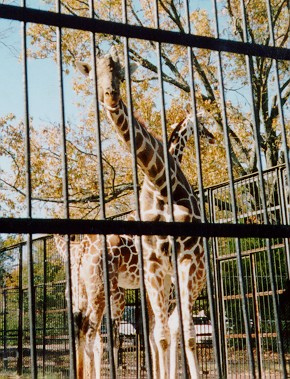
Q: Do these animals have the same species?
A: Yes, all the animals are giraffes.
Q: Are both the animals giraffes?
A: Yes, all the animals are giraffes.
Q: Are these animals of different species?
A: No, all the animals are giraffes.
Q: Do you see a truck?
A: No, there are no trucks.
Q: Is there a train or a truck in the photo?
A: No, there are no trucks or trains.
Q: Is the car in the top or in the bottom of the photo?
A: The car is in the bottom of the image.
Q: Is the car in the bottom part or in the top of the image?
A: The car is in the bottom of the image.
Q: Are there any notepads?
A: No, there are no notepads.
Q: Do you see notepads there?
A: No, there are no notepads.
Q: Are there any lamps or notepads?
A: No, there are no notepads or lamps.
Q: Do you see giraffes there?
A: Yes, there is a giraffe.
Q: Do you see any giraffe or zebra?
A: Yes, there is a giraffe.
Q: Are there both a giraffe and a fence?
A: Yes, there are both a giraffe and a fence.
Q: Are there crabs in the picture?
A: No, there are no crabs.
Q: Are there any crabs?
A: No, there are no crabs.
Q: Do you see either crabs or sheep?
A: No, there are no crabs or sheep.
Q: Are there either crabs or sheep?
A: No, there are no crabs or sheep.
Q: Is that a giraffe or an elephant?
A: That is a giraffe.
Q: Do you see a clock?
A: No, there are no clocks.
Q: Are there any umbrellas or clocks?
A: No, there are no clocks or umbrellas.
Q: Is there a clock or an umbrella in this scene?
A: No, there are no clocks or umbrellas.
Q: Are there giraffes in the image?
A: Yes, there is a giraffe.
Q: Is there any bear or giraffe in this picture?
A: Yes, there is a giraffe.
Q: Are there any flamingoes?
A: No, there are no flamingoes.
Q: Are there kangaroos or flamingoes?
A: No, there are no flamingoes or kangaroos.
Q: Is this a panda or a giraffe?
A: This is a giraffe.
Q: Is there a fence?
A: Yes, there is a fence.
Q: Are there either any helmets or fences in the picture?
A: Yes, there is a fence.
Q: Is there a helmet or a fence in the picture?
A: Yes, there is a fence.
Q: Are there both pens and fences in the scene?
A: No, there is a fence but no pens.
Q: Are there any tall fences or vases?
A: Yes, there is a tall fence.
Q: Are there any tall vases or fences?
A: Yes, there is a tall fence.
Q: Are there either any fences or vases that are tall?
A: Yes, the fence is tall.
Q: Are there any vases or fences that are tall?
A: Yes, the fence is tall.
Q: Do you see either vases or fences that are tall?
A: Yes, the fence is tall.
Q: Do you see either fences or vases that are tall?
A: Yes, the fence is tall.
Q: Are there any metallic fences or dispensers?
A: Yes, there is a metal fence.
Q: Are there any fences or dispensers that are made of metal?
A: Yes, the fence is made of metal.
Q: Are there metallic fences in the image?
A: Yes, there is a metal fence.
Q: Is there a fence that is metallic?
A: Yes, there is a fence that is metallic.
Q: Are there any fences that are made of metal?
A: Yes, there is a fence that is made of metal.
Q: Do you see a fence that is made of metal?
A: Yes, there is a fence that is made of metal.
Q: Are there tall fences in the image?
A: Yes, there is a tall fence.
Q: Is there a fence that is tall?
A: Yes, there is a fence that is tall.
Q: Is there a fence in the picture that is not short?
A: Yes, there is a tall fence.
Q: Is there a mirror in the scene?
A: No, there are no mirrors.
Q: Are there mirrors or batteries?
A: No, there are no mirrors or batteries.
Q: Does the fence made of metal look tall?
A: Yes, the fence is tall.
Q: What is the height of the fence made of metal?
A: The fence is tall.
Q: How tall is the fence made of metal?
A: The fence is tall.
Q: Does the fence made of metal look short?
A: No, the fence is tall.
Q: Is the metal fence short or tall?
A: The fence is tall.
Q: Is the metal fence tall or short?
A: The fence is tall.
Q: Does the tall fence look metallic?
A: Yes, the fence is metallic.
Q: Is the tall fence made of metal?
A: Yes, the fence is made of metal.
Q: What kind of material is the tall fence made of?
A: The fence is made of metal.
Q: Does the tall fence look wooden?
A: No, the fence is metallic.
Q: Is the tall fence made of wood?
A: No, the fence is made of metal.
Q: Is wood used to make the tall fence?
A: No, the fence is made of metal.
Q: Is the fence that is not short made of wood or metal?
A: The fence is made of metal.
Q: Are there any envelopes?
A: No, there are no envelopes.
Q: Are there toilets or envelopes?
A: No, there are no envelopes or toilets.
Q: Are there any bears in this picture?
A: No, there are no bears.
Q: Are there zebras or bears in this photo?
A: No, there are no bears or zebras.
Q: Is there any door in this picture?
A: Yes, there is a door.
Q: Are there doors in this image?
A: Yes, there is a door.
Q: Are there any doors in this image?
A: Yes, there is a door.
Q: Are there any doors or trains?
A: Yes, there is a door.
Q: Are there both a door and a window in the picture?
A: No, there is a door but no windows.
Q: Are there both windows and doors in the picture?
A: No, there is a door but no windows.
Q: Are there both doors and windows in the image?
A: No, there is a door but no windows.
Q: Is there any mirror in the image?
A: No, there are no mirrors.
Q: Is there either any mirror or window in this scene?
A: No, there are no mirrors or windows.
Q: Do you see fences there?
A: Yes, there is a fence.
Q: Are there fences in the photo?
A: Yes, there is a fence.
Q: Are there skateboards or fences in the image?
A: Yes, there is a fence.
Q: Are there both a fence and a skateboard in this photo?
A: No, there is a fence but no skateboards.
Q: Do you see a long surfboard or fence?
A: Yes, there is a long fence.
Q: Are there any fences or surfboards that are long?
A: Yes, the fence is long.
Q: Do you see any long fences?
A: Yes, there is a long fence.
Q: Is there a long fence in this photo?
A: Yes, there is a long fence.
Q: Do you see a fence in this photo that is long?
A: Yes, there is a long fence.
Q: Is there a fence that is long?
A: Yes, there is a fence that is long.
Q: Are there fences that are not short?
A: Yes, there is a long fence.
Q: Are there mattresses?
A: No, there are no mattresses.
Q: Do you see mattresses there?
A: No, there are no mattresses.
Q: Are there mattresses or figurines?
A: No, there are no mattresses or figurines.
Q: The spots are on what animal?
A: The spots are on the giraffe.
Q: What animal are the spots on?
A: The spots are on the giraffe.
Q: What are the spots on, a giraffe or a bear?
A: The spots are on a giraffe.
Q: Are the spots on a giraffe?
A: Yes, the spots are on a giraffe.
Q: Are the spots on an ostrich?
A: No, the spots are on a giraffe.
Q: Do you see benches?
A: No, there are no benches.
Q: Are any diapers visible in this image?
A: No, there are no diapers.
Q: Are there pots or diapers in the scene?
A: No, there are no diapers or pots.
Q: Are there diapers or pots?
A: No, there are no diapers or pots.